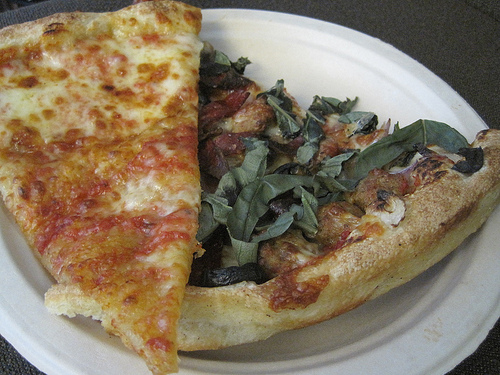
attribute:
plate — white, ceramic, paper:
[0, 6, 497, 373]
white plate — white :
[246, 8, 481, 103]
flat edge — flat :
[449, 324, 497, 369]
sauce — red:
[37, 169, 128, 251]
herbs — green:
[213, 97, 462, 231]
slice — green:
[167, 56, 448, 326]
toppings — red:
[261, 99, 398, 203]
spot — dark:
[277, 279, 311, 303]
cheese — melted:
[7, 20, 192, 336]